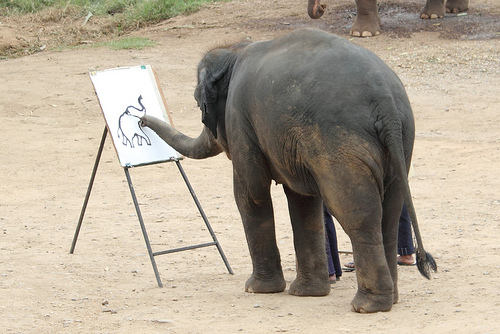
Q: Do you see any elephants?
A: Yes, there is an elephant.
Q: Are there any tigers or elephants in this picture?
A: Yes, there is an elephant.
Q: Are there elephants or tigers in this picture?
A: Yes, there is an elephant.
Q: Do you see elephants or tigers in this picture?
A: Yes, there is an elephant.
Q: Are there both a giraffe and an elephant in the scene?
A: No, there is an elephant but no giraffes.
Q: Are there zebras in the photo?
A: No, there are no zebras.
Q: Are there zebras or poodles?
A: No, there are no zebras or poodles.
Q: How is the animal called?
A: The animal is an elephant.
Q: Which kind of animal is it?
A: The animal is an elephant.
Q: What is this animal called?
A: This is an elephant.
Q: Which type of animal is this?
A: This is an elephant.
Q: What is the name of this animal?
A: This is an elephant.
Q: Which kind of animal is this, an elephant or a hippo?
A: This is an elephant.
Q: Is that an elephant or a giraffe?
A: That is an elephant.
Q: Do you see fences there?
A: No, there are no fences.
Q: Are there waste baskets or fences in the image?
A: No, there are no fences or waste baskets.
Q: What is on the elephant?
A: The dirt is on the elephant.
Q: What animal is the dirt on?
A: The dirt is on the elephant.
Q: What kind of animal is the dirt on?
A: The dirt is on the elephant.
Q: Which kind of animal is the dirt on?
A: The dirt is on the elephant.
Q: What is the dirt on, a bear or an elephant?
A: The dirt is on an elephant.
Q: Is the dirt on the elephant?
A: Yes, the dirt is on the elephant.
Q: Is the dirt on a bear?
A: No, the dirt is on the elephant.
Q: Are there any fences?
A: No, there are no fences.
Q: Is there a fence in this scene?
A: No, there are no fences.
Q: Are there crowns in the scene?
A: No, there are no crowns.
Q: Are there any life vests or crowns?
A: No, there are no crowns or life vests.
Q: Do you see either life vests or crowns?
A: No, there are no crowns or life vests.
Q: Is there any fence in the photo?
A: No, there are no fences.